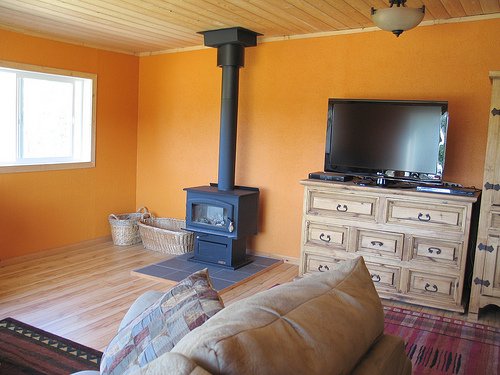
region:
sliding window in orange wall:
[2, 55, 102, 180]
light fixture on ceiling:
[357, 2, 442, 40]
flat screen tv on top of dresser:
[318, 90, 455, 187]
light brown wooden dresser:
[295, 174, 484, 312]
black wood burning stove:
[169, 23, 266, 271]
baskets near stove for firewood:
[104, 204, 191, 258]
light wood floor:
[27, 257, 138, 326]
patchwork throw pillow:
[99, 271, 220, 372]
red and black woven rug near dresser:
[405, 302, 478, 373]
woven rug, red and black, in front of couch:
[2, 314, 89, 369]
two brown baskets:
[91, 182, 238, 294]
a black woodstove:
[147, 143, 295, 280]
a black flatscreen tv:
[306, 61, 453, 208]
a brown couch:
[136, 245, 416, 362]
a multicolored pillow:
[96, 258, 256, 373]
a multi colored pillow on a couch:
[101, 259, 329, 371]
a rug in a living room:
[323, 269, 495, 373]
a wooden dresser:
[276, 158, 496, 308]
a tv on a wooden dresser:
[278, 68, 498, 327]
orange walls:
[138, 43, 493, 186]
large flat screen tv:
[320, 88, 450, 183]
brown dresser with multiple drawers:
[292, 171, 474, 311]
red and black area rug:
[405, 310, 495, 372]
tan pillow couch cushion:
[250, 265, 380, 366]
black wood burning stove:
[180, 166, 256, 267]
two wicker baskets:
[97, 202, 188, 252]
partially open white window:
[1, 53, 103, 176]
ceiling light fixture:
[360, 0, 436, 43]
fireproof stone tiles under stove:
[142, 245, 258, 290]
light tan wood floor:
[44, 267, 115, 316]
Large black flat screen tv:
[316, 92, 454, 195]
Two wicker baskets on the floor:
[98, 198, 195, 261]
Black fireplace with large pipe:
[173, 26, 269, 272]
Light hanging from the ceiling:
[353, 0, 444, 42]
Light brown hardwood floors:
[23, 266, 118, 321]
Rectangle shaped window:
[0, 49, 107, 188]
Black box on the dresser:
[409, 182, 479, 204]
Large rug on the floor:
[374, 295, 499, 373]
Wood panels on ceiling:
[61, 6, 184, 56]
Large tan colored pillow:
[173, 251, 394, 372]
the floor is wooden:
[35, 236, 130, 321]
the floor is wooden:
[56, 218, 231, 364]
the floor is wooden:
[65, 246, 156, 356]